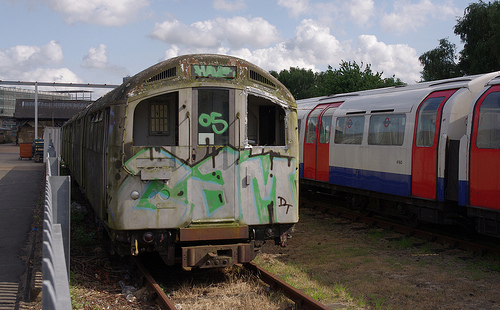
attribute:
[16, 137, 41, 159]
bin — red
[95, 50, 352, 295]
train — blue, white and red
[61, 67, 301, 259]
train — old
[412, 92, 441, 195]
paint — red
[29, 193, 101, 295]
barrier — blue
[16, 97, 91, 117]
cover — black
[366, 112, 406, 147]
window — large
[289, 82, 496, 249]
train — newer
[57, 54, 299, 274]
discarded train — rusted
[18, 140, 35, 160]
container — orange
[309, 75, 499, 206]
train — new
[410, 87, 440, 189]
door — red